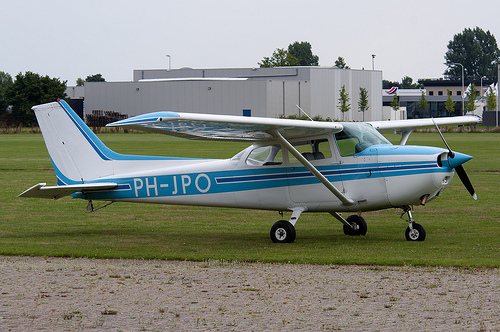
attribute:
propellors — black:
[431, 116, 454, 156]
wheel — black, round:
[266, 217, 298, 250]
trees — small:
[335, 85, 349, 118]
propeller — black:
[431, 117, 477, 202]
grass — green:
[42, 189, 223, 250]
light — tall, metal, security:
[440, 58, 475, 124]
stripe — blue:
[56, 100, 109, 160]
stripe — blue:
[106, 115, 159, 125]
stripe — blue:
[214, 162, 439, 185]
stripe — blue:
[55, 177, 130, 189]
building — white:
[120, 46, 394, 146]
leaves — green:
[438, 16, 500, 81]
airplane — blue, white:
[10, 88, 484, 250]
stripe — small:
[206, 149, 446, 201]